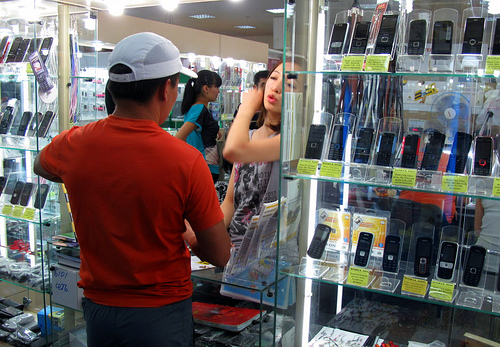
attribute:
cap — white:
[100, 26, 202, 86]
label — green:
[341, 57, 364, 72]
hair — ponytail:
[172, 68, 225, 109]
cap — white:
[88, 32, 220, 85]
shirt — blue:
[36, 118, 220, 303]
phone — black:
[305, 186, 476, 291]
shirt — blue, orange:
[34, 106, 228, 305]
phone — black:
[376, 130, 394, 165]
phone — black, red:
[288, 103, 330, 181]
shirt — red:
[52, 110, 247, 333]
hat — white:
[106, 27, 192, 98]